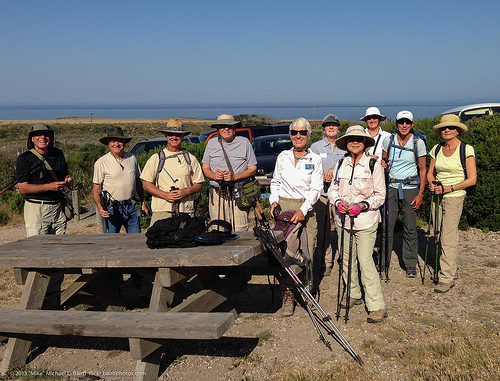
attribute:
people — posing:
[15, 105, 478, 323]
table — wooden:
[1, 233, 282, 380]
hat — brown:
[157, 117, 191, 136]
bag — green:
[234, 176, 264, 210]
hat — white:
[332, 124, 375, 141]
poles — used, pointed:
[333, 206, 354, 324]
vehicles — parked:
[121, 122, 294, 187]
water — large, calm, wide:
[0, 102, 456, 124]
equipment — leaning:
[250, 224, 363, 369]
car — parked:
[132, 135, 198, 155]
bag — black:
[145, 215, 238, 249]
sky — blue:
[2, 0, 500, 102]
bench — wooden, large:
[2, 307, 235, 380]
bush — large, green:
[464, 115, 497, 230]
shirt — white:
[268, 145, 324, 214]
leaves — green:
[482, 133, 498, 148]